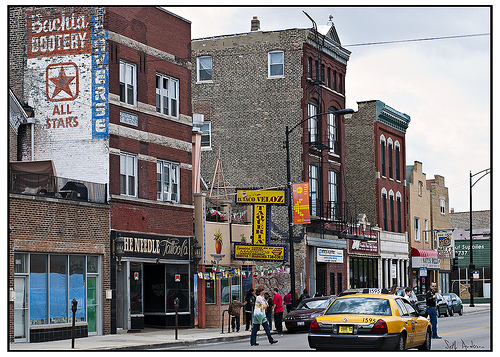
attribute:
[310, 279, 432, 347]
taxicab — Yellow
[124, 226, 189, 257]
restaurant — taqueria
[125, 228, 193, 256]
advertising — Store sign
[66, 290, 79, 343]
meter — Coin-operated parking 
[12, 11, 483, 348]
photo — corner, Signature on the bottom-right 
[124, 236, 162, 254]
sign — The Needle, Shop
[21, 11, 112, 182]
sign — advertising, Converse All Stars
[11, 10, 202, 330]
building — side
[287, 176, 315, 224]
flags — Several Mexican 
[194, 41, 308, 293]
brick — gray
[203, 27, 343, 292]
brick — gray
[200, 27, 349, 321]
building — gray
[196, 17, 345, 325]
brick — gray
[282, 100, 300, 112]
brick — gray,  building's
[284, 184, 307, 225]
banner —  yellow and orange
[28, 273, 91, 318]
tarp —  blue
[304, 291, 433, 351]
taxi —  black and yellow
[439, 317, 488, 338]
line —  yellow,  road's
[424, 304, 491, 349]
road —  light grey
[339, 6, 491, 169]
sky —  grey and white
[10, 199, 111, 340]
store —  abandoned 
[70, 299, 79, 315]
head —  black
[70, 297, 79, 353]
meter —  for parking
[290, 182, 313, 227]
sign —  red and yellow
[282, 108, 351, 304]
lamp —  black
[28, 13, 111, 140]
sign —  fading,   for converse shoes,  red and white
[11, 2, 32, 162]
wall —  brick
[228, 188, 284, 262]
sign —  yellow,  for a taco shop,  yellow and red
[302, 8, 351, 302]
building —  brick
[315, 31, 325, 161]
escape —  metal , for  fire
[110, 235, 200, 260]
sign —  advertising, for tatoo parlor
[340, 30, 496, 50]
wire —  telephone's, in air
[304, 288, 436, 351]
cab —  yellow,  taxi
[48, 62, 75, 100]
star —   red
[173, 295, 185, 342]
meter — for parking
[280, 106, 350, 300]
pole —   black,  street's, for light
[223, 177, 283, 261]
sign — yellow, red